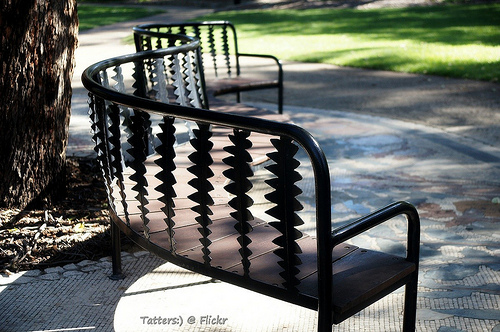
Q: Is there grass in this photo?
A: Yes, there is grass.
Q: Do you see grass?
A: Yes, there is grass.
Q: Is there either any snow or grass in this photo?
A: Yes, there is grass.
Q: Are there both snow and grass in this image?
A: No, there is grass but no snow.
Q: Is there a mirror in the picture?
A: No, there are no mirrors.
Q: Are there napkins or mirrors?
A: No, there are no mirrors or napkins.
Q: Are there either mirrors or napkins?
A: No, there are no mirrors or napkins.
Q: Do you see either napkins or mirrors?
A: No, there are no mirrors or napkins.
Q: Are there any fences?
A: No, there are no fences.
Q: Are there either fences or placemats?
A: No, there are no fences or placemats.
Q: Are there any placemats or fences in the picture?
A: No, there are no fences or placemats.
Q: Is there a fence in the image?
A: No, there are no fences.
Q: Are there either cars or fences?
A: No, there are no fences or cars.